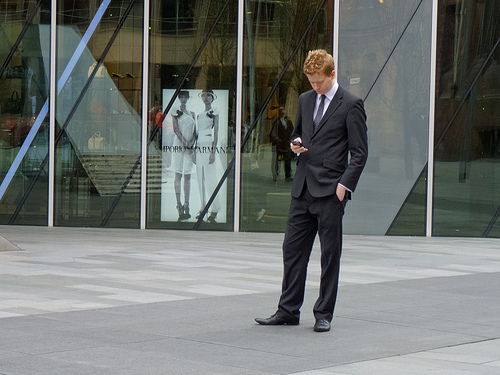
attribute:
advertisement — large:
[158, 88, 231, 224]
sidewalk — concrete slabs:
[0, 222, 487, 369]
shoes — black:
[249, 306, 336, 333]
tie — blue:
[311, 91, 328, 133]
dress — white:
[172, 112, 196, 174]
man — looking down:
[267, 49, 373, 221]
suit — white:
[192, 107, 220, 210]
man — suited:
[254, 49, 366, 331]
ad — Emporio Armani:
[161, 87, 228, 223]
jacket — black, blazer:
[283, 83, 368, 200]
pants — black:
[269, 186, 354, 326]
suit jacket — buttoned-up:
[291, 85, 369, 203]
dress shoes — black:
[251, 304, 334, 333]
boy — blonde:
[255, 50, 371, 333]